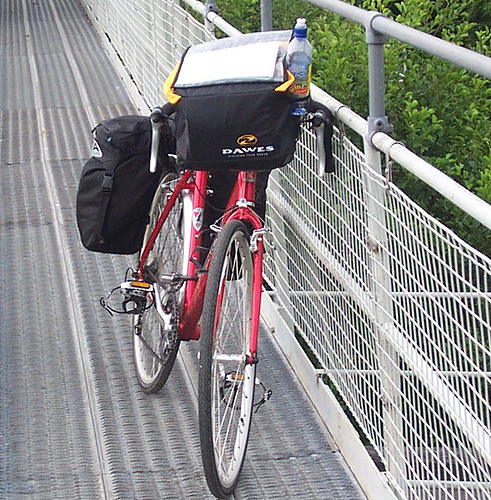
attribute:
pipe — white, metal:
[374, 132, 481, 217]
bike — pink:
[124, 98, 338, 494]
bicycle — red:
[101, 94, 339, 496]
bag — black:
[130, 23, 309, 164]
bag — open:
[162, 38, 308, 182]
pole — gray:
[360, 9, 393, 134]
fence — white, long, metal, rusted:
[85, 2, 489, 495]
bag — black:
[70, 112, 175, 255]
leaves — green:
[218, 0, 489, 253]